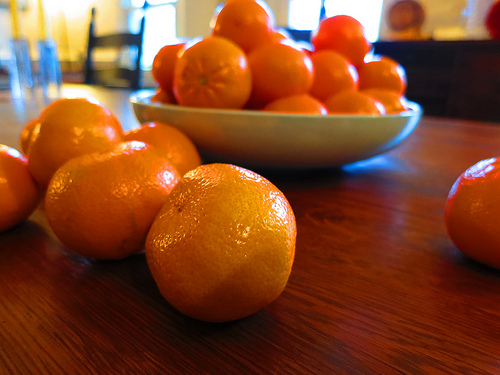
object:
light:
[262, 182, 292, 229]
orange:
[38, 139, 183, 257]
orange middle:
[164, 191, 199, 236]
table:
[314, 213, 421, 345]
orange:
[145, 162, 298, 322]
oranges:
[169, 37, 253, 107]